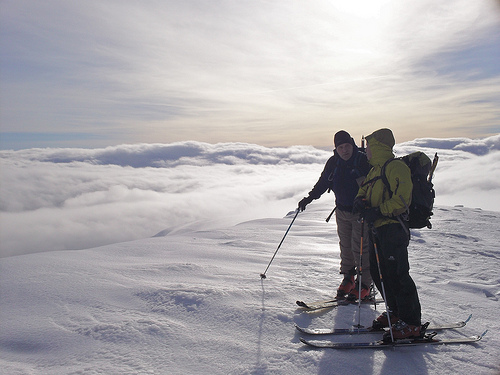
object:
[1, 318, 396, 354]
cliff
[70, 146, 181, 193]
clouds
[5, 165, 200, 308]
cliff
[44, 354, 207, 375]
ground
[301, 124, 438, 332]
talking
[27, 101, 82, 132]
clouds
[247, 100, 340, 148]
sun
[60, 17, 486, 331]
world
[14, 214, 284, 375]
line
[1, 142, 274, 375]
dropoff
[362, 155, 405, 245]
hood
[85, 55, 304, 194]
bright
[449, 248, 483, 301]
snow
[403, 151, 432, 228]
backpack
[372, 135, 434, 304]
wearing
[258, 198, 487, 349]
two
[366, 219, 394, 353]
poles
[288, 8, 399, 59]
sun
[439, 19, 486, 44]
clouds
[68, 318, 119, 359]
snow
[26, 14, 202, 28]
clouds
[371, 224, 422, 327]
pants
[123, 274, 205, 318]
snow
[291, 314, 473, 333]
skis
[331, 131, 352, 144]
hats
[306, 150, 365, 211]
coats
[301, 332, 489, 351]
skis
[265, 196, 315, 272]
poles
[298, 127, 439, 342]
people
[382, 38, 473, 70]
sky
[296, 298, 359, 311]
skis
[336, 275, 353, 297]
boots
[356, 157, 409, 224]
coat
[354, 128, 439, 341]
man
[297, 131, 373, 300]
man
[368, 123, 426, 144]
hat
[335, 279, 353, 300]
sneakers